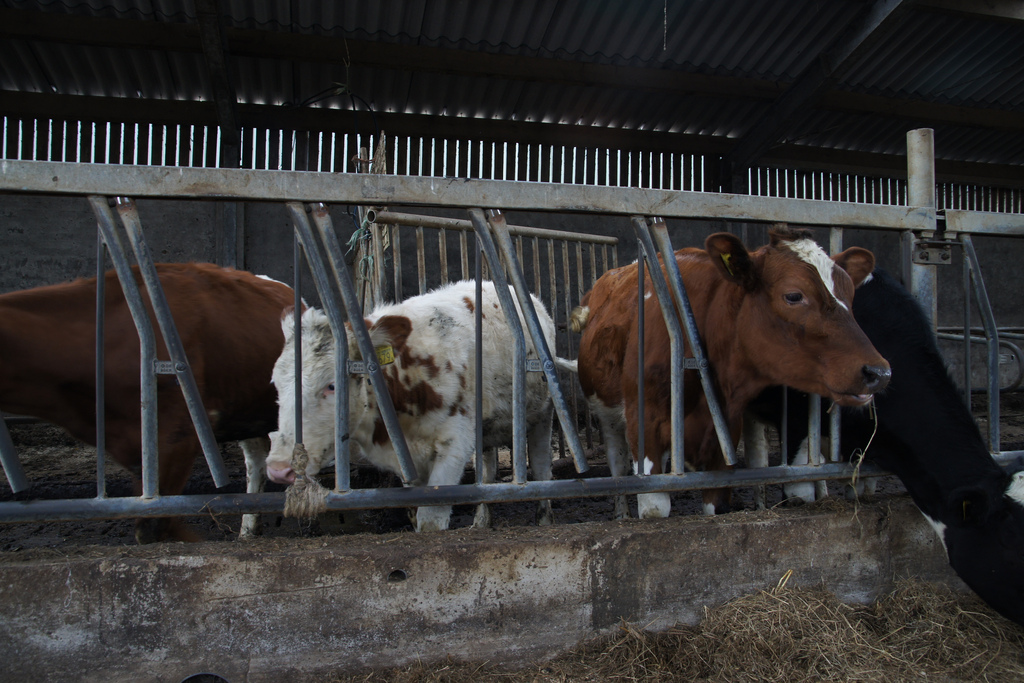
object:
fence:
[6, 146, 1022, 533]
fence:
[13, 135, 990, 496]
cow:
[840, 273, 993, 572]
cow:
[574, 234, 892, 519]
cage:
[0, 113, 1024, 594]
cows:
[9, 227, 1022, 534]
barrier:
[0, 479, 963, 674]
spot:
[764, 215, 854, 304]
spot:
[385, 342, 456, 412]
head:
[933, 450, 993, 606]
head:
[694, 201, 894, 409]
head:
[245, 292, 410, 487]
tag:
[373, 335, 400, 370]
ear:
[362, 310, 422, 360]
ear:
[272, 302, 310, 341]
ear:
[835, 246, 874, 286]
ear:
[930, 481, 987, 527]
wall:
[19, 497, 945, 645]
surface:
[11, 549, 785, 632]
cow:
[272, 280, 561, 533]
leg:
[529, 404, 556, 528]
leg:
[466, 431, 504, 525]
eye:
[322, 381, 339, 395]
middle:
[238, 128, 617, 539]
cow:
[0, 262, 324, 546]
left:
[2, 7, 240, 680]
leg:
[425, 426, 467, 567]